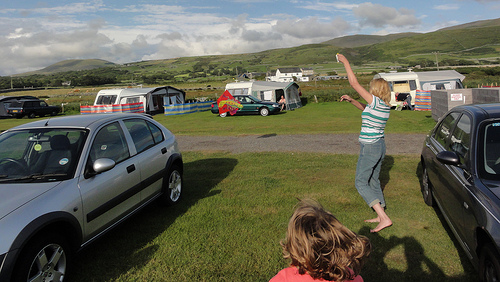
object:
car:
[0, 115, 183, 281]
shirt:
[358, 96, 390, 144]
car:
[419, 104, 499, 282]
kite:
[217, 91, 243, 116]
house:
[268, 67, 310, 83]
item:
[35, 142, 42, 152]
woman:
[335, 51, 394, 233]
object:
[334, 50, 341, 64]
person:
[276, 93, 286, 111]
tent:
[225, 80, 305, 111]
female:
[263, 195, 367, 281]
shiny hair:
[282, 196, 373, 278]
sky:
[0, 0, 500, 74]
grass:
[0, 147, 481, 281]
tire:
[163, 165, 183, 205]